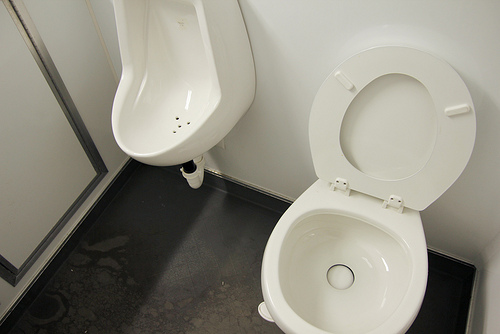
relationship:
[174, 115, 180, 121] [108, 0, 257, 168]
hole in bottom of urinal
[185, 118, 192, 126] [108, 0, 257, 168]
hole in bottom of urinal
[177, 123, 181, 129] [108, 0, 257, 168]
hole in bottom of urinal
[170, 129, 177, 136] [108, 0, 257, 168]
hole in bottom of urinal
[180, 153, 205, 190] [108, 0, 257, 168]
pipe attached to urinal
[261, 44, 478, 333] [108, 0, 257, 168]
toilet next to urinal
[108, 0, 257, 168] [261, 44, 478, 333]
urinal next to toilet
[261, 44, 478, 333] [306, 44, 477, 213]
toilet with toilet seat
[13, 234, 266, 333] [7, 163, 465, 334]
spots on top of floor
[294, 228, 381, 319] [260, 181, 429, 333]
water inside of toilet basin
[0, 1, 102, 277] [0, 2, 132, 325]
door inside of wall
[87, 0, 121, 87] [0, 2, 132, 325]
caulk in corner of wall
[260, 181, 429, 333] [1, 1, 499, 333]
toilet basin inside of bathroom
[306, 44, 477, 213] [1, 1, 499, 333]
toilet seat inside of bathroom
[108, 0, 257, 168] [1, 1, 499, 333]
urinal inside of bathroom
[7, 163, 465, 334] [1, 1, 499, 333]
floor inside of bathroom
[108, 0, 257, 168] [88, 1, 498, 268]
urinal mounted on wall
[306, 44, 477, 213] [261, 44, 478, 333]
toilet seat up on toilet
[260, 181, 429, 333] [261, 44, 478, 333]
toilet basin of toilet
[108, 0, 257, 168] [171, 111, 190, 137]
urinal has drain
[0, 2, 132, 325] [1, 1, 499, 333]
wall of bathroom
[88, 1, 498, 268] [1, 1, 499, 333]
wall of bathroom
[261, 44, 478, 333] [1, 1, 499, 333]
toilet inside of bathroom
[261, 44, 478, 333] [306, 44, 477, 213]
toilet with open toilet seat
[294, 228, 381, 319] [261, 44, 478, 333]
water inside toilet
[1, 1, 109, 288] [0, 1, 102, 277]
frame around door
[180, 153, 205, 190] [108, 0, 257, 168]
pipe underneath urinal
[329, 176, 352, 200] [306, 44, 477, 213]
hinge connecting toilet seat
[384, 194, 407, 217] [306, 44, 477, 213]
hinge connecting toilet seat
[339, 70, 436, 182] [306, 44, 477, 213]
toilet lid under toilet seat